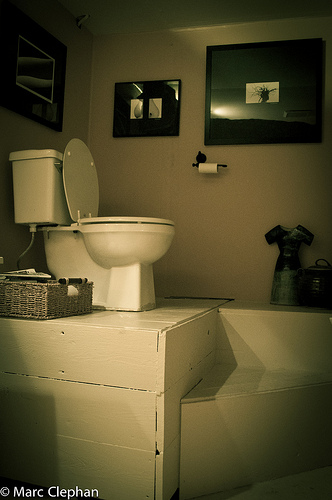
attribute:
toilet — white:
[8, 143, 173, 306]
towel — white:
[190, 159, 229, 175]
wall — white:
[4, 0, 326, 301]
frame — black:
[107, 80, 181, 149]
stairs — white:
[159, 308, 323, 476]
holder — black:
[183, 148, 235, 176]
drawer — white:
[1, 390, 152, 499]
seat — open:
[58, 132, 186, 239]